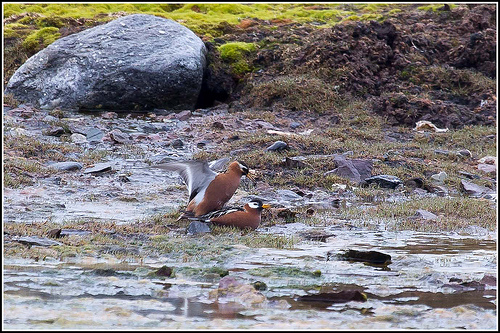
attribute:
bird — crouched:
[203, 196, 269, 228]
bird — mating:
[203, 196, 273, 236]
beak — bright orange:
[261, 198, 269, 208]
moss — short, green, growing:
[2, 2, 462, 75]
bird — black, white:
[205, 192, 269, 230]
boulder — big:
[6, 10, 208, 113]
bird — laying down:
[171, 194, 319, 243]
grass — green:
[350, 174, 483, 229]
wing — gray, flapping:
[145, 156, 206, 216]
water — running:
[365, 235, 454, 289]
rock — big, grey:
[11, 17, 201, 114]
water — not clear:
[3, 103, 498, 328]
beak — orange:
[260, 202, 270, 210]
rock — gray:
[5, 12, 207, 113]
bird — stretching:
[153, 130, 278, 216]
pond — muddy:
[8, 245, 498, 325]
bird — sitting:
[153, 155, 253, 215]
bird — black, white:
[157, 143, 249, 219]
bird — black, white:
[178, 154, 260, 225]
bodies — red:
[170, 150, 284, 270]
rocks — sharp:
[346, 141, 451, 199]